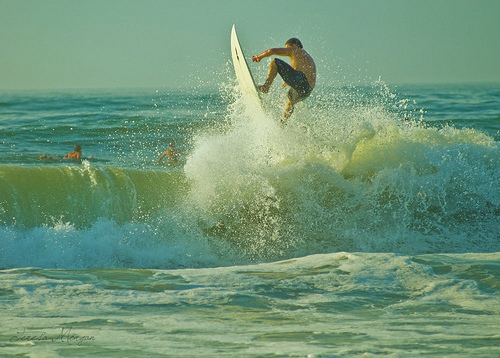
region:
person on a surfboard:
[225, 29, 322, 150]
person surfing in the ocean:
[226, 19, 319, 146]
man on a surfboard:
[225, 21, 323, 133]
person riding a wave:
[220, 25, 326, 148]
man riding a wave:
[217, 20, 309, 137]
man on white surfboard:
[225, 25, 320, 146]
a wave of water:
[7, 166, 497, 239]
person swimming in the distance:
[37, 140, 97, 168]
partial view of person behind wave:
[157, 136, 182, 167]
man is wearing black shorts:
[233, 33, 323, 138]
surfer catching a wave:
[219, 20, 324, 157]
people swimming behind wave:
[47, 128, 177, 175]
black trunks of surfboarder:
[275, 61, 307, 96]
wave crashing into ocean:
[7, 158, 494, 270]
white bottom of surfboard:
[227, 28, 271, 148]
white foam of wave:
[10, 208, 491, 268]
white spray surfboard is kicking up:
[211, 58, 423, 207]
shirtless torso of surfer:
[268, 40, 324, 84]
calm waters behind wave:
[16, 91, 470, 140]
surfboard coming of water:
[223, 26, 269, 129]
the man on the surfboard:
[253, 38, 329, 123]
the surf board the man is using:
[226, 31, 276, 137]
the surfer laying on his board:
[53, 143, 127, 165]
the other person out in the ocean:
[149, 145, 189, 169]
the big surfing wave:
[6, 153, 473, 265]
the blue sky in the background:
[7, 6, 499, 116]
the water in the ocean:
[8, 93, 498, 345]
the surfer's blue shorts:
[272, 68, 319, 101]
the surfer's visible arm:
[248, 44, 298, 61]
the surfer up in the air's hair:
[281, 35, 308, 45]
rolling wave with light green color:
[0, 139, 217, 279]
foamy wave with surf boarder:
[209, 20, 495, 246]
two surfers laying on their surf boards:
[34, 130, 189, 180]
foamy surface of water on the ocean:
[25, 251, 483, 341]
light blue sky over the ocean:
[43, 3, 478, 80]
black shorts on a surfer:
[220, 18, 325, 155]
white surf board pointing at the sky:
[215, 21, 272, 133]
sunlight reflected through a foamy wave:
[338, 100, 414, 163]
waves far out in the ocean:
[7, 81, 172, 120]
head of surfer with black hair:
[275, 29, 310, 55]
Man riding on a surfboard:
[207, 8, 349, 190]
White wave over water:
[178, 124, 338, 222]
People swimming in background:
[42, 127, 194, 187]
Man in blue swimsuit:
[245, 31, 319, 103]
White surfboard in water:
[208, 27, 273, 129]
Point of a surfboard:
[224, 15, 244, 53]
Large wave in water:
[345, 124, 495, 241]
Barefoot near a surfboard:
[241, 70, 292, 137]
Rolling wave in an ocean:
[4, 151, 185, 278]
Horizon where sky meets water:
[14, 73, 176, 115]